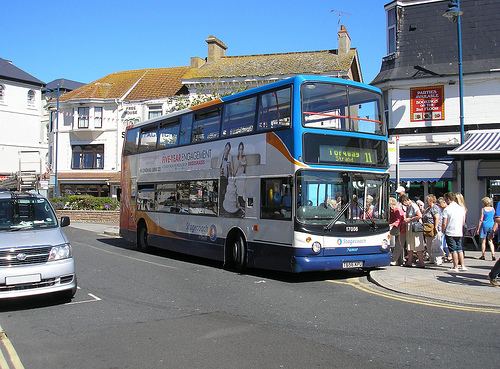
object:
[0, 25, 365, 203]
buildings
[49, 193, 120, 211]
bush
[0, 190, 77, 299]
car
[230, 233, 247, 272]
tire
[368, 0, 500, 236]
building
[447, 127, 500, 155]
awning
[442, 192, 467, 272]
man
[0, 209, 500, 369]
ground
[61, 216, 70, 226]
mirror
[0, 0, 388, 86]
blue sky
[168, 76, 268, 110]
ivy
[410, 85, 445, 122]
sign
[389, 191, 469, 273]
people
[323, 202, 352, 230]
wiper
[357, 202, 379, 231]
wiper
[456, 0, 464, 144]
post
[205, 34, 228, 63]
chimney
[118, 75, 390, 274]
bus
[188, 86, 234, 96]
wall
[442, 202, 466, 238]
shirt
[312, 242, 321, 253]
light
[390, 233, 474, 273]
stop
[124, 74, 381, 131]
level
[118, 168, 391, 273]
level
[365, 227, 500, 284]
bus stop